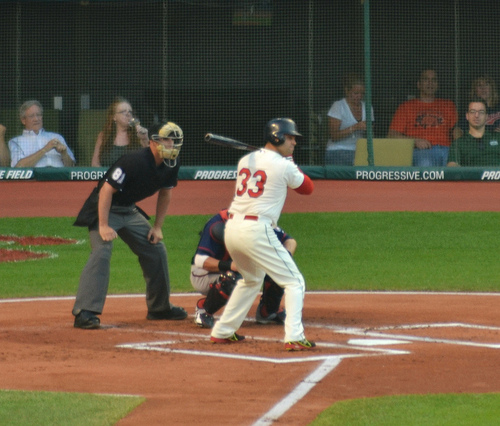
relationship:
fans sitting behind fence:
[0, 65, 499, 164] [1, 1, 499, 169]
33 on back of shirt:
[234, 164, 267, 199] [227, 145, 304, 221]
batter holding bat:
[204, 118, 320, 353] [202, 130, 261, 151]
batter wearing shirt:
[204, 118, 320, 353] [227, 145, 304, 221]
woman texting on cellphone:
[323, 74, 376, 165] [363, 117, 376, 131]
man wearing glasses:
[9, 99, 77, 166] [23, 110, 44, 121]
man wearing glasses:
[444, 96, 498, 164] [467, 107, 489, 117]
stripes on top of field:
[2, 287, 497, 426] [0, 182, 499, 426]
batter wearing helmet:
[204, 118, 320, 353] [263, 116, 303, 146]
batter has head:
[204, 118, 320, 353] [266, 117, 301, 157]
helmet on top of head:
[263, 116, 303, 146] [266, 117, 301, 157]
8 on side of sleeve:
[112, 165, 123, 182] [105, 152, 138, 189]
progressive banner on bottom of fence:
[1, 165, 499, 185] [1, 1, 499, 169]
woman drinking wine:
[90, 94, 150, 171] [128, 115, 144, 136]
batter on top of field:
[204, 118, 320, 353] [0, 182, 499, 426]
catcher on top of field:
[188, 207, 298, 329] [0, 182, 499, 426]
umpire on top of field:
[71, 120, 187, 328] [0, 182, 499, 426]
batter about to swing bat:
[204, 118, 320, 353] [202, 130, 261, 151]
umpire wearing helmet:
[71, 120, 187, 328] [147, 116, 183, 168]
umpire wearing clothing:
[71, 120, 187, 328] [73, 147, 178, 315]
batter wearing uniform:
[204, 118, 320, 353] [208, 148, 314, 342]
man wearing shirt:
[9, 99, 77, 166] [7, 125, 76, 167]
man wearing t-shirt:
[386, 67, 458, 168] [389, 96, 457, 146]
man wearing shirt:
[444, 96, 498, 164] [446, 127, 499, 169]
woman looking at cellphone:
[323, 74, 376, 165] [363, 117, 376, 131]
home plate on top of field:
[349, 335, 411, 348] [0, 182, 499, 426]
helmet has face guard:
[147, 116, 183, 168] [158, 129, 183, 169]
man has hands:
[9, 99, 77, 166] [42, 136, 67, 157]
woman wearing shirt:
[323, 74, 376, 165] [323, 96, 376, 152]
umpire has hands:
[71, 120, 187, 328] [95, 223, 165, 245]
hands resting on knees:
[95, 223, 165, 245] [92, 238, 168, 255]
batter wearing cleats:
[204, 118, 320, 353] [208, 332, 316, 354]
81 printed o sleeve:
[111, 164, 127, 187] [105, 152, 138, 189]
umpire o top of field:
[71, 120, 187, 328] [0, 182, 499, 426]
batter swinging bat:
[204, 118, 320, 353] [202, 130, 261, 151]